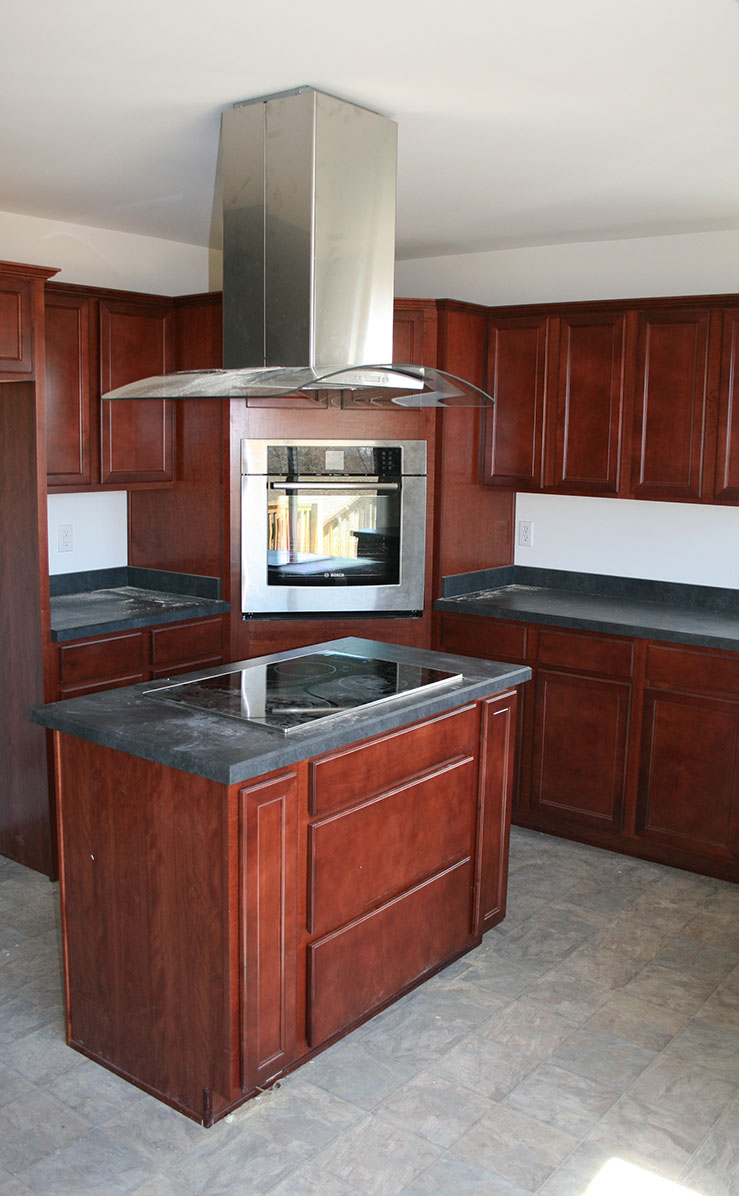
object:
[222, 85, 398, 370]
pipe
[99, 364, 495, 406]
hood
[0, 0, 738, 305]
ceiling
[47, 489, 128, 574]
wall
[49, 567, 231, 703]
counter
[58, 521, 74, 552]
outlet